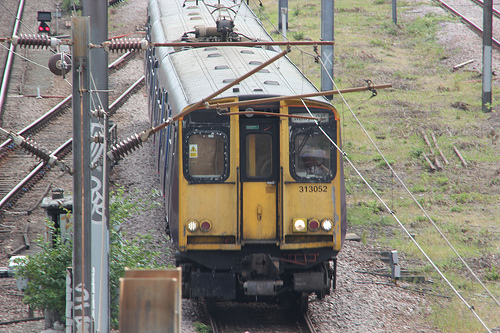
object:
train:
[141, 1, 342, 325]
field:
[340, 5, 499, 327]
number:
[298, 185, 329, 193]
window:
[291, 127, 336, 183]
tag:
[189, 144, 198, 158]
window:
[188, 135, 226, 177]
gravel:
[311, 297, 425, 328]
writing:
[89, 121, 106, 225]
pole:
[72, 1, 107, 332]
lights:
[38, 26, 51, 31]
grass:
[437, 176, 497, 333]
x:
[322, 52, 332, 68]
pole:
[320, 1, 334, 94]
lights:
[290, 217, 333, 233]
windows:
[244, 126, 277, 178]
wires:
[283, 53, 499, 328]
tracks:
[200, 299, 316, 331]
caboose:
[161, 56, 338, 248]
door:
[240, 133, 277, 236]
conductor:
[300, 144, 331, 177]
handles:
[236, 166, 287, 239]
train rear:
[187, 111, 341, 242]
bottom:
[185, 251, 336, 297]